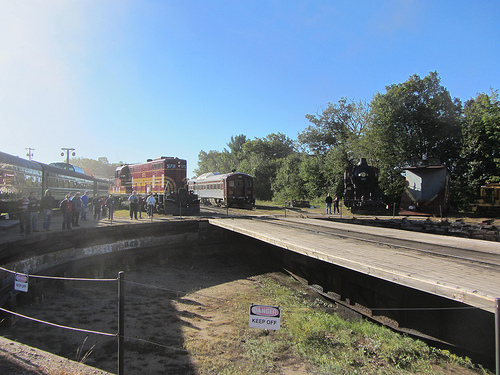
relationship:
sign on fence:
[245, 298, 285, 333] [0, 259, 499, 373]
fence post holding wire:
[109, 263, 128, 372] [0, 263, 495, 371]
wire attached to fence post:
[0, 263, 495, 371] [109, 263, 128, 372]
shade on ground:
[5, 253, 279, 371] [1, 252, 486, 374]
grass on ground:
[4, 253, 480, 373] [1, 252, 486, 374]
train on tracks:
[188, 170, 255, 208] [244, 199, 279, 214]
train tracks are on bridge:
[255, 214, 499, 281] [220, 203, 499, 374]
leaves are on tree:
[361, 75, 464, 170] [361, 69, 460, 192]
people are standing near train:
[15, 188, 161, 244] [1, 148, 110, 222]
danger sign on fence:
[245, 298, 285, 333] [0, 259, 499, 373]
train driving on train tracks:
[188, 170, 255, 208] [255, 214, 499, 281]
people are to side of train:
[15, 188, 161, 244] [1, 148, 110, 222]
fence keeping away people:
[0, 259, 499, 373] [15, 188, 161, 244]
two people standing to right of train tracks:
[127, 187, 158, 221] [255, 214, 499, 281]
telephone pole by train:
[55, 142, 77, 167] [1, 148, 110, 222]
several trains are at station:
[1, 152, 263, 248] [0, 110, 498, 373]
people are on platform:
[15, 188, 161, 244] [1, 207, 195, 277]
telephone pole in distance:
[55, 142, 77, 167] [17, 141, 216, 183]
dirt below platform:
[13, 253, 249, 356] [1, 207, 195, 277]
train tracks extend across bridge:
[255, 214, 499, 281] [220, 203, 499, 374]